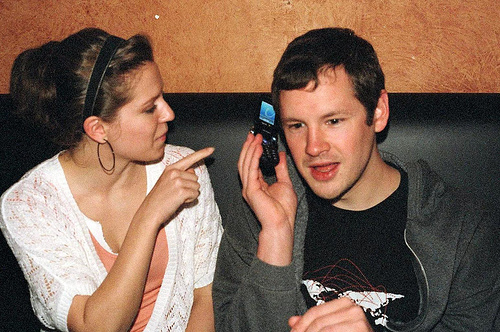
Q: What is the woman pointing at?
A: Phone.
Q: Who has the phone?
A: The man.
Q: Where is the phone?
A: Man's hand.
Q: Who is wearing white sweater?
A: The woman.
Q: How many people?
A: Two.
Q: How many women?
A: One woman.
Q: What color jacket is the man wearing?
A: Gray.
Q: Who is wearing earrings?
A: Woman is wearing earrings.